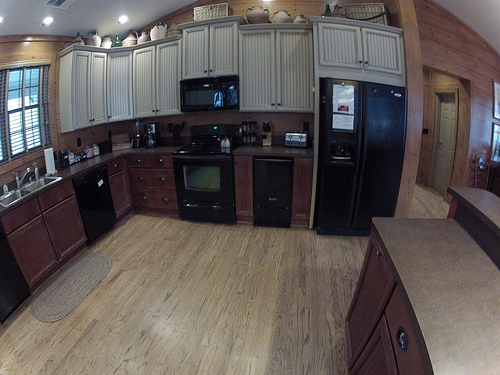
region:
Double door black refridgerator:
[311, 64, 407, 241]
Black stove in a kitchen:
[176, 120, 244, 230]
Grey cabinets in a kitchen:
[61, 38, 340, 114]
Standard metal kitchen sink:
[3, 161, 90, 276]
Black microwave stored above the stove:
[169, 72, 259, 123]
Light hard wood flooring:
[131, 201, 331, 373]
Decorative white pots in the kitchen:
[61, 23, 183, 50]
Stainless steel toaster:
[279, 121, 315, 150]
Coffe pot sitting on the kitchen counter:
[126, 117, 171, 152]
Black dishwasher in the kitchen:
[69, 167, 139, 242]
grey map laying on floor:
[30, 251, 131, 328]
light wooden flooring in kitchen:
[138, 266, 275, 356]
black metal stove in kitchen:
[170, 121, 235, 230]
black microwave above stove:
[174, 70, 246, 112]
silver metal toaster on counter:
[280, 127, 312, 147]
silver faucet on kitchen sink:
[8, 160, 39, 185]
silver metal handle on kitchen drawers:
[387, 329, 412, 356]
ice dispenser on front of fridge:
[321, 139, 361, 165]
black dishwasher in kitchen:
[69, 165, 126, 241]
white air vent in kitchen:
[30, 0, 77, 9]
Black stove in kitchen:
[177, 122, 232, 223]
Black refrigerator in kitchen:
[315, 77, 408, 239]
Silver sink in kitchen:
[0, 165, 62, 209]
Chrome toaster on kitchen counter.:
[286, 130, 308, 148]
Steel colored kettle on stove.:
[215, 132, 238, 154]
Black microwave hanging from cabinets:
[177, 75, 244, 116]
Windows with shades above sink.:
[0, 63, 53, 163]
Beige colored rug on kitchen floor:
[30, 245, 115, 326]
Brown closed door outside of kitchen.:
[425, 87, 458, 195]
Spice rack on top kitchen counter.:
[236, 115, 259, 152]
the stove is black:
[172, 158, 245, 229]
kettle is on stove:
[189, 135, 237, 152]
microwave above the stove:
[176, 79, 243, 241]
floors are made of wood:
[135, 275, 290, 352]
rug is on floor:
[37, 240, 125, 352]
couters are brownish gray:
[401, 223, 486, 351]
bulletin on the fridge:
[318, 75, 355, 237]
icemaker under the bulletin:
[327, 80, 359, 181]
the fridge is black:
[325, 81, 392, 232]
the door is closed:
[430, 70, 457, 210]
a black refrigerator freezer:
[315, 77, 404, 237]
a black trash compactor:
[250, 154, 290, 227]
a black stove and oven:
[172, 122, 237, 222]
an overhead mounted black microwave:
[177, 76, 239, 115]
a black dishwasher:
[67, 163, 117, 247]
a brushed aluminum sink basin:
[2, 162, 62, 209]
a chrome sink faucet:
[10, 165, 32, 190]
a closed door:
[427, 76, 459, 204]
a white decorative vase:
[145, 21, 169, 46]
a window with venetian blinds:
[4, 65, 46, 157]